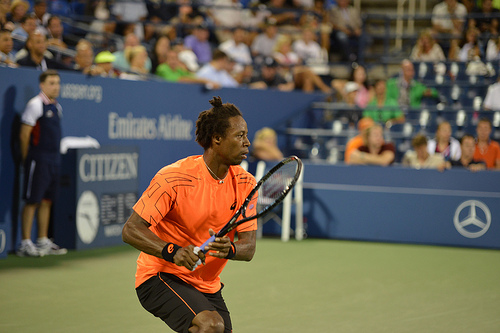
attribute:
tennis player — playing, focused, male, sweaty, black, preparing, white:
[113, 93, 303, 332]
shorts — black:
[137, 269, 233, 332]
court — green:
[4, 220, 499, 332]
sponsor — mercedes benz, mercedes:
[451, 197, 492, 242]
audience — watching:
[0, 4, 499, 168]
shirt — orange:
[132, 146, 258, 299]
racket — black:
[199, 147, 304, 270]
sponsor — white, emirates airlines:
[105, 110, 193, 151]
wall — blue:
[2, 66, 330, 275]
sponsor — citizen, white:
[78, 148, 141, 184]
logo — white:
[55, 77, 108, 112]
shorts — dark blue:
[23, 157, 64, 202]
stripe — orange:
[25, 162, 39, 197]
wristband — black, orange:
[159, 242, 183, 260]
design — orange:
[163, 241, 176, 255]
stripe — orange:
[156, 273, 197, 319]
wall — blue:
[250, 157, 499, 249]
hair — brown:
[35, 70, 60, 84]